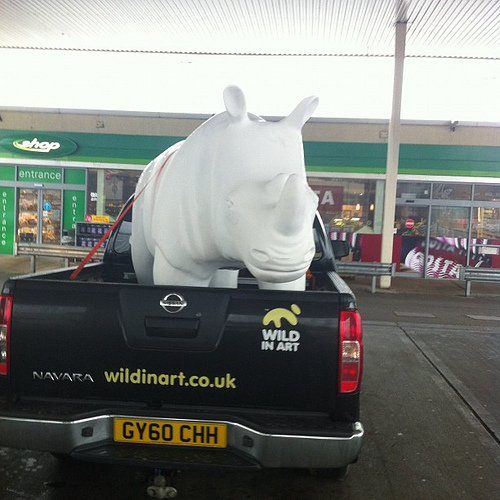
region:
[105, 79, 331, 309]
a white plastic rhino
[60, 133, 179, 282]
a red strap on a rhino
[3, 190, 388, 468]
a black truck carrying a rhino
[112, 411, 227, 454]
a license plate on the back of a truck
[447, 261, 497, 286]
railing in front of a store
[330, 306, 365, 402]
a tail light on a truck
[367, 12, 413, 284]
a tall white metal post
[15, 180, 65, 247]
sliding doors on a store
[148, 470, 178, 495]
a ball hitch on the back of a truck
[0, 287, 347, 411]
a tailgate on the back of a truck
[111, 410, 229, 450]
a yellow license plate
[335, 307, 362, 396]
a red tail light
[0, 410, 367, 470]
a silver metal bumper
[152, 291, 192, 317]
a logo on the truck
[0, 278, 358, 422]
the bed door of a truck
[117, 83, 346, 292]
a white rhino statue in the truck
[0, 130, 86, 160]
a green shop sign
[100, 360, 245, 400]
yellow letters on the truck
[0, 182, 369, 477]
a black truck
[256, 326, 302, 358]
white letters on the truck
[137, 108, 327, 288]
a sculpture of a rhino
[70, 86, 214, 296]
the sculpture is held down my a red strap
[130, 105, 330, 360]
the sculpture is in the bed of a truck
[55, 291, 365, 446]
the truck is black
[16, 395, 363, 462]
back fender is metal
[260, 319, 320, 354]
WILD IN ART is on the back of the truck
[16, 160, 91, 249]
entrance to the store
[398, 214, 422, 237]
red circle with a white line through it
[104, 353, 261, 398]
wildinart.co.uk is in yellow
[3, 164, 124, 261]
entrance written around the doors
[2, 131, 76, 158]
green and white backlit sign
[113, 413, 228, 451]
yellow and black license plate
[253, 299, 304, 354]
bumper sticker reading "Wild in Art"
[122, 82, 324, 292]
large white rhino sculpture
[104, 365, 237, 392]
website address for artist on truck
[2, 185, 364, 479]
black nissan navara truck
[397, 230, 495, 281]
berry pink and white ad poster in window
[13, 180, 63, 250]
electric sliding glass double doors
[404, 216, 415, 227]
red and white caution sign reflected in window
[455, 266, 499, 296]
guard rail protecting building front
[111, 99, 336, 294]
White rhinoceros statue in back of truck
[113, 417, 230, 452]
Black and yellow license plate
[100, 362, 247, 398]
Yellow website address on tailgate of truck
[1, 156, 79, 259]
Entrance to shop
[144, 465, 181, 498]
Trailer hitch on the back of the truck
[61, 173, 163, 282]
Red strap holding down rhino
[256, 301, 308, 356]
White and yellow sticker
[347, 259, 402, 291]
Metal guard railing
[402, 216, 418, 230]
Do not enter sign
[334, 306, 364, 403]
Red tail light